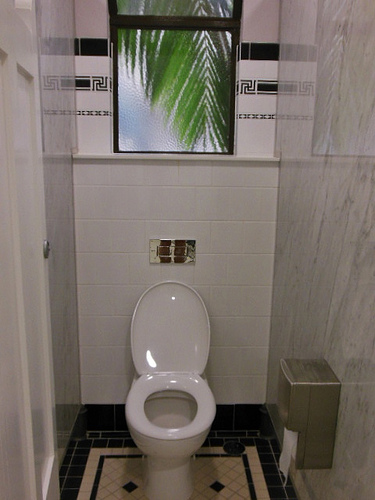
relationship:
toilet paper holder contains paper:
[274, 355, 344, 471] [277, 427, 302, 492]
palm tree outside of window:
[118, 0, 231, 153] [104, 0, 244, 159]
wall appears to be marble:
[271, 0, 372, 311] [265, 0, 372, 499]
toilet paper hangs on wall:
[277, 427, 302, 492] [265, 0, 372, 499]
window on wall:
[104, 0, 244, 159] [35, 0, 317, 431]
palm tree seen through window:
[118, 0, 231, 153] [104, 0, 244, 159]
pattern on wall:
[39, 74, 317, 122] [38, 35, 317, 159]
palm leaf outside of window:
[118, 0, 231, 153] [104, 0, 244, 159]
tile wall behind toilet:
[44, 162, 283, 407] [123, 279, 220, 500]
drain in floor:
[228, 440, 246, 457] [60, 427, 302, 500]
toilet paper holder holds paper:
[274, 355, 344, 471] [277, 427, 302, 492]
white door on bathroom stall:
[3, 2, 66, 499] [3, 0, 374, 500]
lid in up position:
[129, 277, 214, 380] [128, 279, 212, 375]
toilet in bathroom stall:
[123, 279, 220, 500] [3, 0, 374, 500]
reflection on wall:
[118, 0, 231, 153] [35, 0, 317, 431]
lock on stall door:
[41, 238, 53, 261] [3, 2, 66, 499]